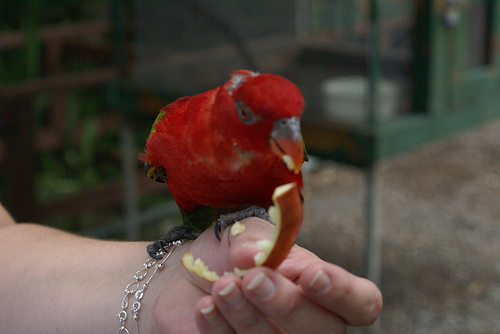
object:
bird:
[140, 69, 305, 254]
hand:
[151, 213, 386, 332]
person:
[2, 203, 385, 334]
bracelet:
[115, 240, 181, 334]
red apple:
[181, 182, 303, 295]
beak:
[272, 118, 307, 175]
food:
[284, 153, 299, 173]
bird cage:
[117, 0, 497, 313]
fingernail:
[245, 272, 274, 300]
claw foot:
[144, 221, 203, 261]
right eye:
[237, 106, 251, 122]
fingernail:
[221, 284, 247, 308]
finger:
[303, 261, 385, 323]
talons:
[214, 205, 274, 242]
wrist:
[100, 235, 196, 334]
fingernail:
[199, 307, 225, 325]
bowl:
[325, 77, 413, 121]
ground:
[102, 118, 500, 332]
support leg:
[362, 165, 389, 331]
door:
[424, 3, 496, 116]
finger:
[241, 268, 345, 333]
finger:
[212, 272, 274, 333]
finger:
[194, 294, 225, 333]